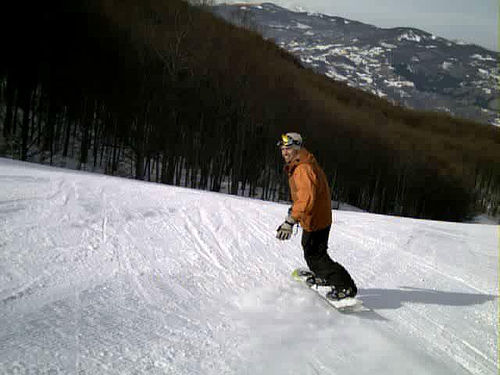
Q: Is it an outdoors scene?
A: Yes, it is outdoors.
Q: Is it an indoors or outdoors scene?
A: It is outdoors.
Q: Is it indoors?
A: No, it is outdoors.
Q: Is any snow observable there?
A: Yes, there is snow.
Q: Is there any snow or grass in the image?
A: Yes, there is snow.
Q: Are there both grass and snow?
A: No, there is snow but no grass.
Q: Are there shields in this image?
A: No, there are no shields.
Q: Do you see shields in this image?
A: No, there are no shields.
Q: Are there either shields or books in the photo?
A: No, there are no shields or books.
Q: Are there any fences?
A: No, there are no fences.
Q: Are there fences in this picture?
A: No, there are no fences.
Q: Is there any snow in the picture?
A: Yes, there is snow.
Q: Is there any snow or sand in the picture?
A: Yes, there is snow.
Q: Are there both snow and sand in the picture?
A: No, there is snow but no sand.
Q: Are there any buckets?
A: No, there are no buckets.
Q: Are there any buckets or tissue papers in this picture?
A: No, there are no buckets or tissue papers.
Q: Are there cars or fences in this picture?
A: No, there are no fences or cars.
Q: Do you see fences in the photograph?
A: No, there are no fences.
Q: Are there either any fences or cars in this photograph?
A: No, there are no fences or cars.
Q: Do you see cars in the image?
A: No, there are no cars.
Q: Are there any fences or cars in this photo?
A: No, there are no cars or fences.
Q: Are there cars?
A: No, there are no cars.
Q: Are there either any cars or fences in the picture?
A: No, there are no cars or fences.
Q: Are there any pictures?
A: No, there are no pictures.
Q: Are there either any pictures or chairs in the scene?
A: No, there are no pictures or chairs.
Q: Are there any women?
A: No, there are no women.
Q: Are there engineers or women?
A: No, there are no women or engineers.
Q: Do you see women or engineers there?
A: No, there are no women or engineers.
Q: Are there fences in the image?
A: No, there are no fences.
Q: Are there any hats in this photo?
A: Yes, there is a hat.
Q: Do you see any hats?
A: Yes, there is a hat.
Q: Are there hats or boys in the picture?
A: Yes, there is a hat.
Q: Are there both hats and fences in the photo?
A: No, there is a hat but no fences.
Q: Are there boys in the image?
A: No, there are no boys.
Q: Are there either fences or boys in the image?
A: No, there are no boys or fences.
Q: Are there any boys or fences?
A: No, there are no boys or fences.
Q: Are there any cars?
A: No, there are no cars.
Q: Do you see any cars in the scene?
A: No, there are no cars.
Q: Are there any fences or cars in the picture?
A: No, there are no cars or fences.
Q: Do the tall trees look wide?
A: Yes, the trees are wide.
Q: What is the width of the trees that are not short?
A: The trees are wide.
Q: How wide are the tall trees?
A: The trees are wide.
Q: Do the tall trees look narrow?
A: No, the trees are wide.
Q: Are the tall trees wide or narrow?
A: The trees are wide.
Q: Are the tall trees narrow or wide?
A: The trees are wide.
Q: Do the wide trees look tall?
A: Yes, the trees are tall.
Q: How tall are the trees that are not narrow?
A: The trees are tall.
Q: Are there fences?
A: No, there are no fences.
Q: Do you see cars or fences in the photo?
A: No, there are no fences or cars.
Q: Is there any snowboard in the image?
A: Yes, there is a snowboard.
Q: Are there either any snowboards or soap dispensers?
A: Yes, there is a snowboard.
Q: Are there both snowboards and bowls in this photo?
A: No, there is a snowboard but no bowls.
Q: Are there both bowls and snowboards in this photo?
A: No, there is a snowboard but no bowls.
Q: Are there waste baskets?
A: No, there are no waste baskets.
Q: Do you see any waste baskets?
A: No, there are no waste baskets.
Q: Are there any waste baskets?
A: No, there are no waste baskets.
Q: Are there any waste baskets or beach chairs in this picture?
A: No, there are no waste baskets or beach chairs.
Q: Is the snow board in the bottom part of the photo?
A: Yes, the snow board is in the bottom of the image.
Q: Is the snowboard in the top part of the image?
A: No, the snowboard is in the bottom of the image.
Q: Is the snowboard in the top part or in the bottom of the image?
A: The snowboard is in the bottom of the image.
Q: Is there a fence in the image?
A: No, there are no fences.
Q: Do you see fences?
A: No, there are no fences.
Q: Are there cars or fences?
A: No, there are no fences or cars.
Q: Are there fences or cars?
A: No, there are no fences or cars.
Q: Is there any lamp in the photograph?
A: No, there are no lamps.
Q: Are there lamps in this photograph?
A: No, there are no lamps.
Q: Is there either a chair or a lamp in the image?
A: No, there are no lamps or chairs.